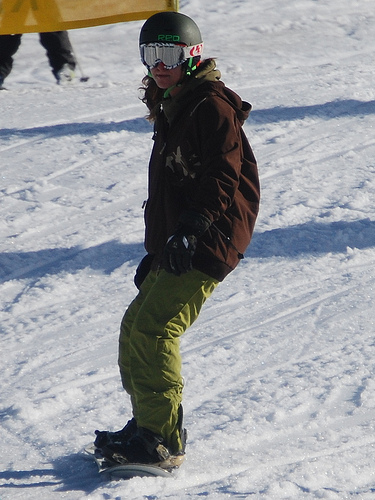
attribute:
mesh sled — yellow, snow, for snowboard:
[90, 418, 193, 485]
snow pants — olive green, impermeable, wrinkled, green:
[105, 247, 222, 444]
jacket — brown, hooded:
[123, 61, 269, 291]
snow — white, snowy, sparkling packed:
[9, 6, 374, 485]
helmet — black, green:
[132, 6, 212, 56]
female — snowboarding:
[72, 0, 276, 490]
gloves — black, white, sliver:
[122, 227, 210, 292]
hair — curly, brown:
[130, 68, 170, 129]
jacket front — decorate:
[148, 129, 202, 190]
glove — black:
[149, 223, 217, 291]